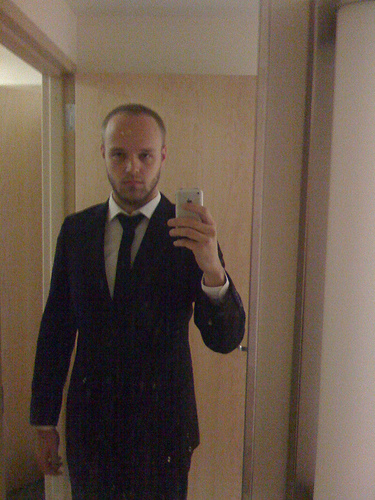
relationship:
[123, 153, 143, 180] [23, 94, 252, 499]
nose of man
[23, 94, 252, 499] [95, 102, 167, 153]
man has hair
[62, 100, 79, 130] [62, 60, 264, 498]
hinge of door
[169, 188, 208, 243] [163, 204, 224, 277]
cellphone in hand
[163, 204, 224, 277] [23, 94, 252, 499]
hand of man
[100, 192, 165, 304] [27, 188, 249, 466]
shirt under coat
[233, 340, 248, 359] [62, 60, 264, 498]
handle of door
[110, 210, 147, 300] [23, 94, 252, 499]
tie on man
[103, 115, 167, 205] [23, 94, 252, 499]
face on man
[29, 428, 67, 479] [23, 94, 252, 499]
hand on man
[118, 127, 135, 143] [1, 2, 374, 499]
dirt on mirror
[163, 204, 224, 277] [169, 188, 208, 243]
hand holding cellphone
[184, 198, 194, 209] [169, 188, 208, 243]
logo on cellphone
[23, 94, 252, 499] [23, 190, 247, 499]
man in suit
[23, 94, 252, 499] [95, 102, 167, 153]
man with hair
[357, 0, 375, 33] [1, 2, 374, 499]
edge of mirror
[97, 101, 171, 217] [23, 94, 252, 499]
head of man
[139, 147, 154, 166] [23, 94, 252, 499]
eyes of man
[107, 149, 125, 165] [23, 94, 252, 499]
eyes of man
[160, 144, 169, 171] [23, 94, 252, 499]
ear of man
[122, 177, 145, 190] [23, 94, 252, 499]
lips of man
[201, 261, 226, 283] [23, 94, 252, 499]
wrist of man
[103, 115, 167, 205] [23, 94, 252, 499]
face of man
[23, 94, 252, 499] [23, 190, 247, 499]
man wearing suit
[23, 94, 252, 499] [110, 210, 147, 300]
man wearing tie